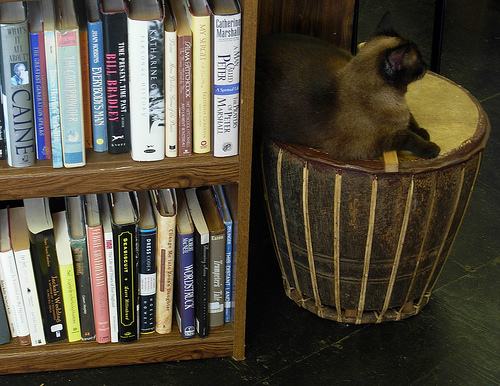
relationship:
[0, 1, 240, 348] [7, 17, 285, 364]
books in bookcase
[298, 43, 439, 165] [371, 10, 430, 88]
cat has a head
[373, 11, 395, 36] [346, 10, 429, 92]
ear on head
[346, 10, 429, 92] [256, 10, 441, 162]
head of cat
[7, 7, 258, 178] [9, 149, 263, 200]
books on shelf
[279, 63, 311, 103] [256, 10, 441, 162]
fur on cat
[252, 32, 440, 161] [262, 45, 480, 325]
cat on top of drum